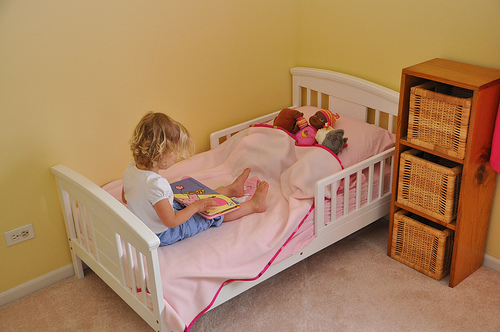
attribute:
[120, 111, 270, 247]
girl — young, reading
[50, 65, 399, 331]
bed — white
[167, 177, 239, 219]
book — cute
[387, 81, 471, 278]
baskets — wicker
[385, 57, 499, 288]
shelving unit — wooden, three level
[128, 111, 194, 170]
hair — blonde, curly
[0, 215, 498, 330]
carpet — pink, beige, soft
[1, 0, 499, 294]
walls — yellow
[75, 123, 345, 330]
blanket — pink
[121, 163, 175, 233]
shirt — white